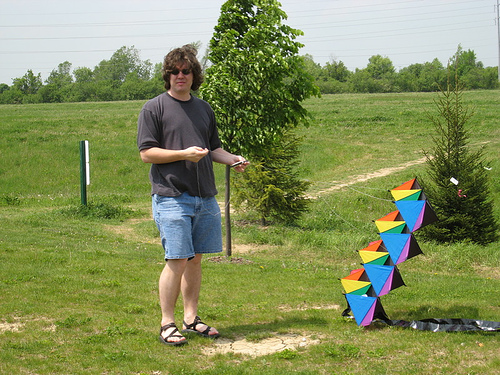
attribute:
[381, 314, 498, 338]
black tails — black 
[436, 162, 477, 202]
tag — white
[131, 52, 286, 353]
guy — content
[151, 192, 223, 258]
shorts — jean 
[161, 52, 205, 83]
hair — long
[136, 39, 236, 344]
t-shirt — black 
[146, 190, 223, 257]
shorts — jean , blue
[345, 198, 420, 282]
kite — rainbow colored